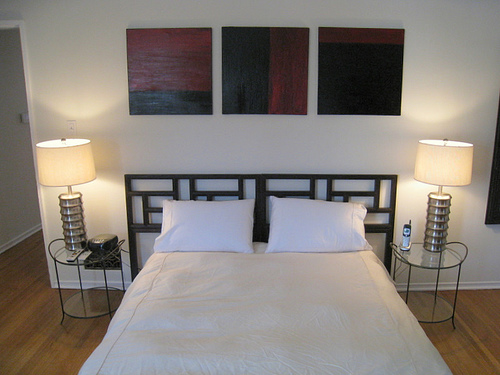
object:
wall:
[1, 1, 498, 293]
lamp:
[416, 138, 475, 186]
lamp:
[34, 135, 98, 187]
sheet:
[78, 242, 454, 372]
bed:
[80, 172, 454, 373]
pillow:
[153, 200, 255, 254]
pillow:
[266, 193, 371, 253]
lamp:
[36, 137, 99, 250]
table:
[47, 238, 126, 324]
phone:
[404, 220, 412, 248]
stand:
[403, 239, 415, 250]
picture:
[126, 27, 211, 116]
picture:
[221, 26, 311, 117]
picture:
[319, 26, 405, 119]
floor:
[1, 228, 497, 374]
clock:
[88, 232, 119, 253]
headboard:
[123, 173, 401, 282]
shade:
[35, 137, 98, 187]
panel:
[21, 113, 30, 125]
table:
[386, 238, 469, 331]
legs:
[52, 260, 65, 325]